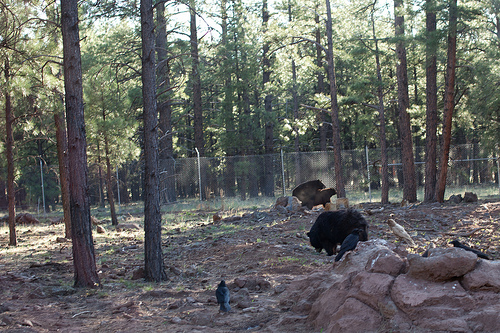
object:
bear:
[304, 208, 368, 257]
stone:
[363, 246, 407, 275]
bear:
[291, 178, 327, 201]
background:
[2, 0, 499, 332]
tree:
[43, 1, 106, 289]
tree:
[182, 0, 218, 199]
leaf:
[93, 49, 105, 56]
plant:
[200, 11, 270, 191]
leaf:
[82, 49, 89, 58]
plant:
[81, 55, 142, 226]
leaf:
[93, 79, 103, 87]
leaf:
[84, 50, 96, 58]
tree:
[135, 1, 169, 283]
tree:
[392, 0, 420, 203]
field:
[0, 183, 500, 332]